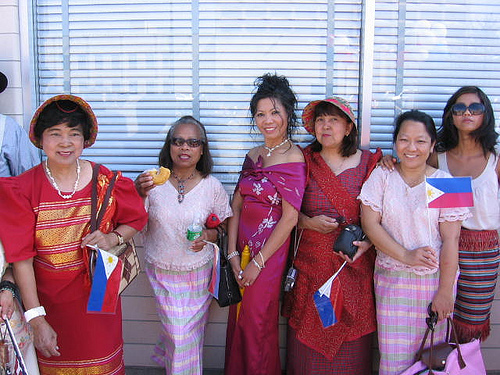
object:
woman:
[132, 113, 234, 375]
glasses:
[449, 101, 484, 118]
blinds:
[29, 0, 362, 209]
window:
[19, 0, 373, 207]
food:
[142, 165, 171, 187]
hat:
[300, 95, 357, 138]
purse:
[396, 302, 488, 375]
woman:
[372, 84, 500, 343]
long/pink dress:
[222, 152, 309, 375]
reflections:
[32, 0, 360, 206]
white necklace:
[41, 155, 81, 199]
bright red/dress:
[81, 318, 104, 337]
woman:
[278, 95, 383, 375]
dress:
[0, 158, 151, 375]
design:
[249, 182, 265, 198]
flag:
[84, 248, 124, 315]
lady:
[0, 93, 147, 375]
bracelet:
[22, 305, 47, 324]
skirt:
[145, 257, 218, 375]